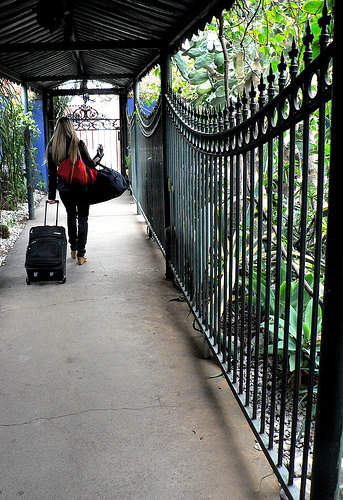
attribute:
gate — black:
[128, 0, 342, 497]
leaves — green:
[0, 0, 342, 371]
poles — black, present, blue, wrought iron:
[0, 0, 342, 500]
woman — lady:
[46, 117, 105, 265]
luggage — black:
[25, 167, 129, 283]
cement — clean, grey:
[0, 175, 295, 499]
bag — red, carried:
[56, 158, 98, 183]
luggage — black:
[24, 201, 68, 287]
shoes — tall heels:
[71, 248, 87, 265]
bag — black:
[79, 167, 129, 205]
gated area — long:
[1, 0, 341, 499]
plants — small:
[0, 100, 38, 212]